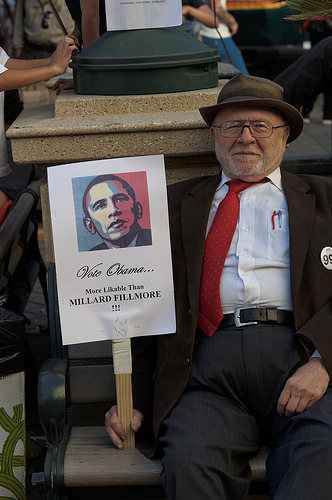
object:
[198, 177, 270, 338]
tie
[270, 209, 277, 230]
ink pens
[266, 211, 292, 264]
shirt pocket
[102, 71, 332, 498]
man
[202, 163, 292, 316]
dress shirt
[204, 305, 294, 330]
belt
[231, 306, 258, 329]
silver buckle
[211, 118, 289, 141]
glasses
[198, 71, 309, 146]
hat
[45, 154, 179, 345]
poster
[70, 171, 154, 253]
obama image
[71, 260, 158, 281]
vote obama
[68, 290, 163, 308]
millard fillimore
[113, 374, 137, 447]
handle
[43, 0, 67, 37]
strap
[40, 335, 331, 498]
bench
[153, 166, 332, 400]
jacket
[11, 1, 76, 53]
shirt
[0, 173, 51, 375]
other bench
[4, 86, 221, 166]
concrete pillar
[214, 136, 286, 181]
beard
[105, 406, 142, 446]
right hand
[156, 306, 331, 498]
pants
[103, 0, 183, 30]
part sign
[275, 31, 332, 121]
trouser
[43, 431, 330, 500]
lower part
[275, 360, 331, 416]
left hand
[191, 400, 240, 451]
part